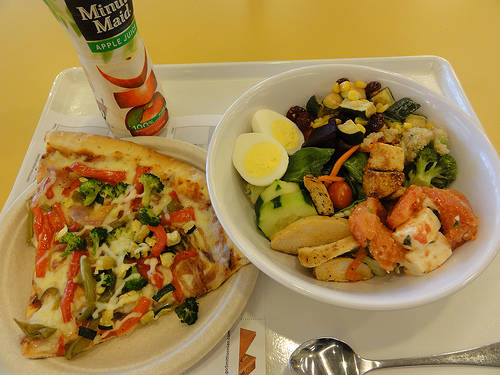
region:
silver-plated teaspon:
[275, 329, 498, 374]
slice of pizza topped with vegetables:
[13, 119, 210, 364]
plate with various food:
[222, 67, 499, 285]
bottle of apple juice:
[33, 2, 194, 139]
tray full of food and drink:
[8, 2, 497, 373]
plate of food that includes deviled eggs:
[221, 72, 499, 313]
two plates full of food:
[0, 74, 476, 349]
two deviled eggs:
[216, 107, 305, 187]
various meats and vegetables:
[277, 103, 453, 276]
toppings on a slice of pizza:
[53, 174, 168, 304]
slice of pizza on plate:
[8, 147, 218, 337]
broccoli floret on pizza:
[170, 299, 202, 332]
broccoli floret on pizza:
[126, 272, 143, 293]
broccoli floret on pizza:
[97, 272, 118, 287]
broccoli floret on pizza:
[134, 207, 156, 224]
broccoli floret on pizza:
[136, 170, 158, 205]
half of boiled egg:
[231, 131, 286, 186]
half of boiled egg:
[244, 104, 306, 152]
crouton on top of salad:
[356, 143, 407, 168]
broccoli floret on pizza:
[58, 237, 81, 255]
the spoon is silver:
[269, 318, 492, 373]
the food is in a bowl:
[215, 60, 494, 310]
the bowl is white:
[197, 57, 494, 322]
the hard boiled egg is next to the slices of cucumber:
[235, 105, 303, 223]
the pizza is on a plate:
[27, 110, 214, 372]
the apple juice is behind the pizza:
[50, 9, 192, 126]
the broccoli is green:
[74, 171, 126, 206]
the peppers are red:
[53, 252, 80, 322]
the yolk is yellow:
[235, 135, 282, 179]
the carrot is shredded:
[317, 145, 355, 184]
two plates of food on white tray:
[10, 63, 492, 343]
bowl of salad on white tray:
[204, 63, 497, 293]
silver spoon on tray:
[287, 334, 498, 374]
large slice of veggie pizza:
[21, 128, 220, 367]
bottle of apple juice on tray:
[39, 0, 181, 135]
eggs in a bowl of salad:
[228, 106, 306, 186]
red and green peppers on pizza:
[24, 198, 65, 342]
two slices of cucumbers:
[255, 179, 316, 223]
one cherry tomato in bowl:
[324, 178, 356, 210]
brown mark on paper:
[210, 300, 273, 370]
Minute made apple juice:
[39, 2, 176, 132]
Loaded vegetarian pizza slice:
[26, 122, 227, 364]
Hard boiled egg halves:
[227, 95, 304, 187]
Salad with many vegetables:
[278, 75, 464, 289]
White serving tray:
[11, 40, 498, 368]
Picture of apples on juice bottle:
[98, 52, 168, 133]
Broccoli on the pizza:
[132, 173, 179, 225]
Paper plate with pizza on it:
[10, 149, 264, 373]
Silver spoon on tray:
[283, 324, 495, 372]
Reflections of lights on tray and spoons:
[270, 330, 389, 374]